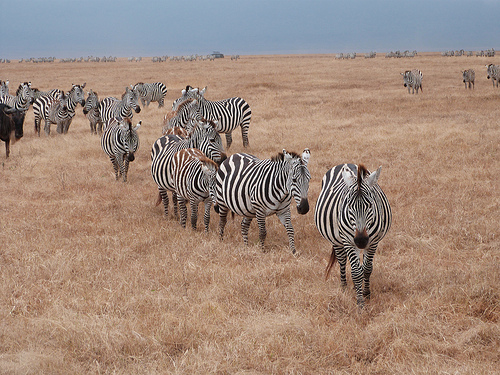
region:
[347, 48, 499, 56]
elephants roaming the grass lands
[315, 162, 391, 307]
a zebra roaming the African plains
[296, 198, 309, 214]
a zebras black nose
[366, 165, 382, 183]
the white ears of the zebra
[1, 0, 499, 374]
the grassy African plains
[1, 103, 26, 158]
a wildebeast within the zebra herd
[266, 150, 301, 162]
the brown hair on the zebras mane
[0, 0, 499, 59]
the blue sky over the African plains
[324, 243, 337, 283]
the long brown hair on the zebras tail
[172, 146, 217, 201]
brown and black zebra stripes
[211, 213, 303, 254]
4 LEGS FO STANDING ZEBRA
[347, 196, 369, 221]
FACE STRIPES OF ZEBRA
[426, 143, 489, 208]
BROWN DRY GRASS ON THE PLANES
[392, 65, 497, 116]
ZEBRAS WALKING ON GRASS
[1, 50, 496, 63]
HERD OF ZEBRAS ON THE PLAINS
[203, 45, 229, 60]
SAFARI VEHICLE VIEWING ZEBRA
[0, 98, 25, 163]
BROWN ANIMAL GRAZING WITH ZEBRA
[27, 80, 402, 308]
HERD OF ZEBRA MOVING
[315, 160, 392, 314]
ZEBRA WALKING TOWARDS CAMERA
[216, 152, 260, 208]
REAR END OF ZEBRA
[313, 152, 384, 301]
A zebra in front of the herd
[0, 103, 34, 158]
A cow walking with the zebra's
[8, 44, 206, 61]
A group of animals in the distance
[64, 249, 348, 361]
Brown dried up grass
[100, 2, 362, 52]
A blue cloudless sky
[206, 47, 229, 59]
a truck driving beside a group of animals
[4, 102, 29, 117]
Horns on a cow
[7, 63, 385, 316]
A herd of zebras walking in the grass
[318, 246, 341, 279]
The tip of a zebras tail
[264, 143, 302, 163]
the mane of a zebra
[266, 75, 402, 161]
Burnt Grass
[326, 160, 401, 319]
Zebra looking at the camera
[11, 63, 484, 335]
A herd of zebras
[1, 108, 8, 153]
An animal that does not seem like is a zebra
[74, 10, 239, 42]
Sky in the background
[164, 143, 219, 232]
zebra that appears to have some brown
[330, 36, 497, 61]
Zebras that are very far away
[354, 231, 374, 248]
The nose of the zebra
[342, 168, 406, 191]
Ears of the zebra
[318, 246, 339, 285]
Tail of the zebra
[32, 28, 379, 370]
Picture is taken outside.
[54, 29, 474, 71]
Picture is taken during the day.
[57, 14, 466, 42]
The sky is medium blue in color.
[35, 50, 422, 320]
Many zebras are on the plains.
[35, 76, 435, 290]
The zebras are walking.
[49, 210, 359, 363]
The grass is dry.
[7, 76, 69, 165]
Various animals are on the grass.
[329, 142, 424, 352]
The zebra has white and black stripes.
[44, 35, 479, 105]
No trees are visible on the plains.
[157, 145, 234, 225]
This zebra's head is down.